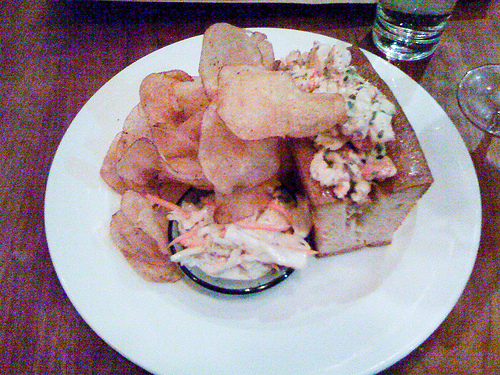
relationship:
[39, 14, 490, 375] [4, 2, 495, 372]
plate on table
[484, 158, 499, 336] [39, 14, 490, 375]
shadow of plate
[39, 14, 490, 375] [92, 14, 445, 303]
plate with food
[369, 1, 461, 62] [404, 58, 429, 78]
glass has shadow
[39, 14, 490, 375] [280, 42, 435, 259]
plate has bun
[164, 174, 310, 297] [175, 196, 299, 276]
bowl with coleslaw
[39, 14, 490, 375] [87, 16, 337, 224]
plate with chips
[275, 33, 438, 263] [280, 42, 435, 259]
bun filled with bun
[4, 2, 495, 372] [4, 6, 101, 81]
table color brown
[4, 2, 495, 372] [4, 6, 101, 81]
table made from wood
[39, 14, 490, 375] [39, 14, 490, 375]
plate seen a plate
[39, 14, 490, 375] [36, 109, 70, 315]
plate has edge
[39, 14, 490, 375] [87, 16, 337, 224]
plate has a side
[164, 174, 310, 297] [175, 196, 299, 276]
bowl has a part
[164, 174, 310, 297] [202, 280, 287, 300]
bowl has edge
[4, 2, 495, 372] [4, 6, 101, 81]
table seen a part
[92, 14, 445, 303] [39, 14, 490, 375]
food on plate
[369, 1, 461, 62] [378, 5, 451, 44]
glass has water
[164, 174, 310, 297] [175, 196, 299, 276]
cup of coleslaw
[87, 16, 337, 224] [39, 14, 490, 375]
chips are on a plate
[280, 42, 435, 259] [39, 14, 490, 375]
bun on plate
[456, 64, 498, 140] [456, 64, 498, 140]
bottom of bottom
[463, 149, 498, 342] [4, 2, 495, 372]
shadow on table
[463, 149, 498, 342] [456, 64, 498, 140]
shadow of bottom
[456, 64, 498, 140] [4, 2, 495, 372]
bottom on table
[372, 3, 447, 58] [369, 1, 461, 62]
water in bottle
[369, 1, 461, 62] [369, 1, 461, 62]
water in cup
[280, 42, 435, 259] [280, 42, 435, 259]
bun between bun